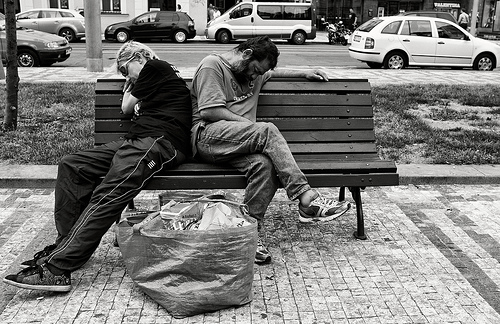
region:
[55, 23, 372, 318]
Men sitting on a bench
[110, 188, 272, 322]
Bag sitting on ground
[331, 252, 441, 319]
Pavement made of bricks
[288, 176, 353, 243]
Tennis shoe on man's foot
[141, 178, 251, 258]
Stuff inside the bag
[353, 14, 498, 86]
Car parked beside the curb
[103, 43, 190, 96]
Man has blonde hair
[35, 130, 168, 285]
Man wearing striped pants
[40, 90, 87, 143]
The grass is short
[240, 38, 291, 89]
Man has dark hair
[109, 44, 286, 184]
People sleeping on the bench.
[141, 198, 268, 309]
A bag in front of the bench.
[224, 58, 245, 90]
Man has facial hair.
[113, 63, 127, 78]
The person is wearing glasses.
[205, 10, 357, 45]
A van parked across the street.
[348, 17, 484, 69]
A small white car on the road.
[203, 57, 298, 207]
Man is sleepin on bench.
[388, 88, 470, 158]
Grass behind the bench.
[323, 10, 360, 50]
A motorcycle parked on side of road.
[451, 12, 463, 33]
Person walking in front of store.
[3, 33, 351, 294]
Two people on a bench.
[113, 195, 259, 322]
A plastic bag on the ground.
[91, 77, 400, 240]
A bench on the sidewalk.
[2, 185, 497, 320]
Brick on the sidewalk.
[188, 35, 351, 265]
A man sleeping on a bench.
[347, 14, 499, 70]
A car on the street.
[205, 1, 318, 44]
A van on the street.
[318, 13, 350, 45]
A motorcycle in the street.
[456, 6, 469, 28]
A man in the street.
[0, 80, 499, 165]
Grass by the sidewalk.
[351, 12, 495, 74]
car on the road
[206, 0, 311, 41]
car on the road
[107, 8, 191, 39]
car on the road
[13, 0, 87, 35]
car on the road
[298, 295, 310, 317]
brick on the sidewalk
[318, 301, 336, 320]
brick on the sidewalk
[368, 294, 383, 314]
brick on the sidewalk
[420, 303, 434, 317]
brick on the sidewalk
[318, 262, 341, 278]
brick on the sidewalk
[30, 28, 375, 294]
the photo is in black and white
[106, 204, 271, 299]
a bag is between two men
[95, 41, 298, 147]
two men are asleep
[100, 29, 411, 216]
two men are on a benh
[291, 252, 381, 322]
the ground is made of brick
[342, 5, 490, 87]
the car is white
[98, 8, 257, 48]
the car is black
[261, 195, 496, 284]
the man is wearing tennis shoes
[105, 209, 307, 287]
the bag is full of trash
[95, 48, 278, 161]
the man is wearing a black shirt